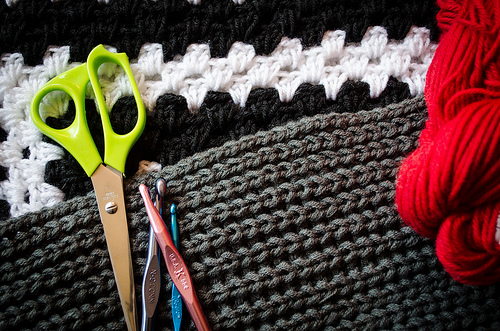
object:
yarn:
[381, 60, 402, 73]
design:
[186, 102, 249, 136]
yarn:
[3, 5, 25, 23]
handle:
[27, 42, 149, 167]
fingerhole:
[32, 86, 77, 132]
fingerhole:
[92, 54, 140, 137]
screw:
[104, 201, 118, 213]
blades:
[92, 177, 133, 330]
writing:
[101, 191, 119, 200]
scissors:
[27, 40, 149, 329]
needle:
[136, 185, 211, 330]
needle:
[165, 200, 188, 331]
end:
[136, 182, 153, 209]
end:
[155, 177, 169, 207]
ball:
[152, 174, 171, 197]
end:
[168, 204, 178, 223]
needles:
[141, 178, 168, 331]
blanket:
[3, 0, 421, 331]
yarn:
[5, 305, 45, 326]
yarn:
[471, 1, 499, 28]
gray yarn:
[378, 307, 420, 329]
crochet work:
[4, 2, 407, 98]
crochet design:
[265, 152, 337, 182]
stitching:
[181, 72, 202, 91]